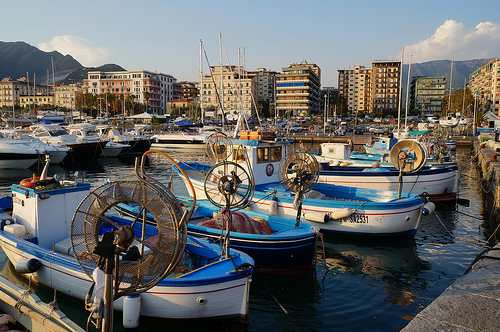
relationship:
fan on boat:
[60, 180, 198, 292] [0, 189, 260, 320]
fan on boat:
[195, 159, 265, 229] [109, 169, 336, 264]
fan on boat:
[374, 129, 445, 187] [272, 131, 464, 208]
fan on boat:
[272, 145, 344, 200] [168, 141, 443, 245]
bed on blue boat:
[119, 193, 319, 240] [100, 182, 320, 270]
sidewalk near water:
[402, 232, 499, 330] [344, 257, 406, 311]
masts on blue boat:
[0, 27, 499, 156] [100, 182, 320, 270]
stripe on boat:
[184, 180, 425, 219] [199, 136, 423, 284]